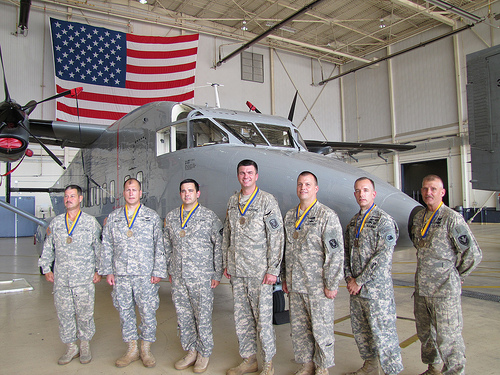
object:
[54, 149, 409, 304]
soldiers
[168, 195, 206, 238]
medal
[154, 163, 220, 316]
soldier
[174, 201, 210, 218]
neck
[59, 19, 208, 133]
flag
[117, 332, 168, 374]
boots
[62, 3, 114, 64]
stars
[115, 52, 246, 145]
stripes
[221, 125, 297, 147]
windshield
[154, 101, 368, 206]
plane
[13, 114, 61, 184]
propeller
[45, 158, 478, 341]
men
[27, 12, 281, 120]
wall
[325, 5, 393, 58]
beams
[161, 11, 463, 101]
ceiling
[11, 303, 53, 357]
floor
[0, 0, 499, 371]
building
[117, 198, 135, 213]
ribbon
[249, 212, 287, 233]
patch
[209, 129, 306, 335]
man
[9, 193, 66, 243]
doors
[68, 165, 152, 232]
windows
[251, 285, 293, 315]
wheels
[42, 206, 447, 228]
medals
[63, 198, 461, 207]
necks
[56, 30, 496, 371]
hanger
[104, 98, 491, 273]
airplane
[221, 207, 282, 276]
uniform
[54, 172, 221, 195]
haircuts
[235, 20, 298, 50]
light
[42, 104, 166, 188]
right